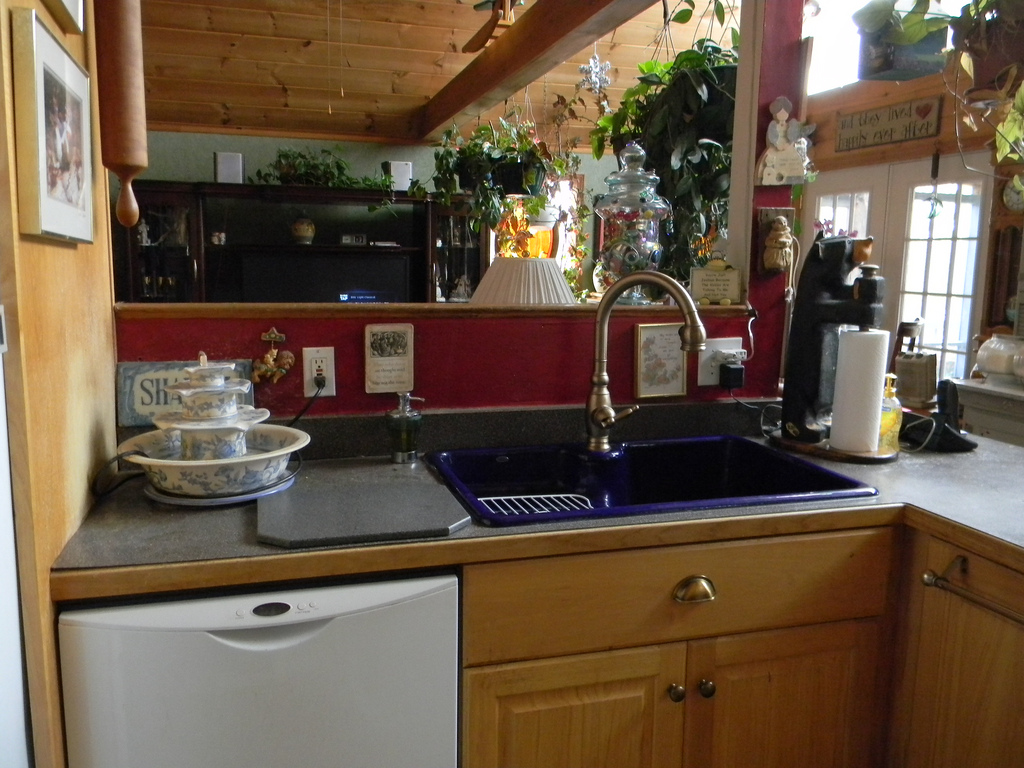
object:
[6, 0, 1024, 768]
kitchen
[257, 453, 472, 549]
chopping board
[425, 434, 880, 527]
sink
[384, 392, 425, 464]
soap dispenser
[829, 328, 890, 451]
paper towel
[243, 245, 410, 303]
tv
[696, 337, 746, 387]
power outlet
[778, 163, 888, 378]
french door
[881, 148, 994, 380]
french door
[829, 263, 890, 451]
holder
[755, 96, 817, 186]
decorative piece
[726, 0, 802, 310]
post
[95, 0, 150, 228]
rolling pin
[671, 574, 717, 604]
pull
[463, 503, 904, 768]
drawer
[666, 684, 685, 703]
knob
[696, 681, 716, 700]
knob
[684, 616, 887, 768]
cabinet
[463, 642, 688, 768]
cabinet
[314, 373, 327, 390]
plug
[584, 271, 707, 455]
faucet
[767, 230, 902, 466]
holder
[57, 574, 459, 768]
dish washer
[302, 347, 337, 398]
electrical outlet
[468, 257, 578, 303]
lamp shade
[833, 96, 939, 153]
sign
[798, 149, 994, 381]
doorway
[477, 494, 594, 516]
rack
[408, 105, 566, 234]
plant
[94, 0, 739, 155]
ceiling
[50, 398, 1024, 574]
counter top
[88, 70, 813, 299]
family room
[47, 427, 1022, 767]
counter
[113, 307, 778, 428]
wall